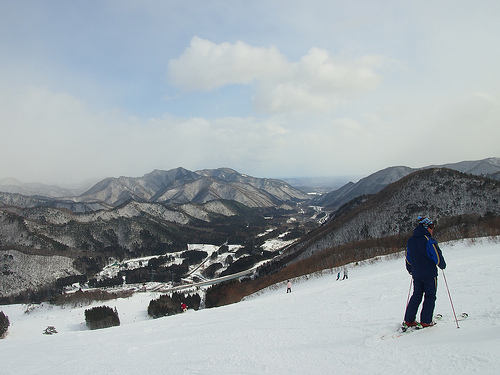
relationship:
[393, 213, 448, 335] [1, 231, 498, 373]
skier on slope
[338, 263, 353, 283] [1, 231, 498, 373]
skier on slope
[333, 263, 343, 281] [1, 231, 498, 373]
skier on slope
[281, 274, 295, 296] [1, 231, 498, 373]
skier on slope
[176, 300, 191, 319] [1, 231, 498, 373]
skier on slope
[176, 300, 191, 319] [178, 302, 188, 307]
skier wearing jacket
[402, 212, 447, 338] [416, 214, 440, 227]
person wearing hat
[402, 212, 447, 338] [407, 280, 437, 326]
person wearing pants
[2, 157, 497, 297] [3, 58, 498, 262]
mountains in distance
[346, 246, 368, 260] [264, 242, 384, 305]
trees bordering ski slope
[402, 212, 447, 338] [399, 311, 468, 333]
person on skis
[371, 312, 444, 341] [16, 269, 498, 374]
skis in snow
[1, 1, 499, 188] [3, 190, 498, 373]
sky above snow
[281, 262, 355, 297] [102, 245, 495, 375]
people on hill